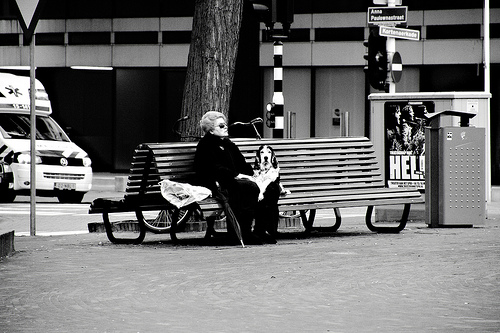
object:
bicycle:
[133, 117, 310, 232]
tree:
[151, 0, 246, 222]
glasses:
[212, 122, 230, 128]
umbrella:
[211, 180, 246, 248]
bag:
[157, 178, 212, 209]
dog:
[251, 143, 291, 201]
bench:
[87, 136, 426, 244]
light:
[374, 52, 384, 64]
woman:
[191, 110, 281, 244]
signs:
[377, 26, 420, 42]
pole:
[384, 0, 396, 93]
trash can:
[423, 109, 487, 228]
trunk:
[181, 0, 243, 141]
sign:
[367, 6, 409, 24]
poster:
[384, 101, 434, 190]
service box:
[366, 91, 492, 202]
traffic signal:
[363, 28, 388, 91]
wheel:
[135, 208, 193, 233]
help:
[389, 154, 426, 180]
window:
[312, 66, 366, 139]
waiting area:
[0, 119, 500, 310]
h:
[388, 155, 400, 179]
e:
[399, 156, 411, 179]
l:
[410, 155, 419, 183]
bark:
[177, 0, 244, 141]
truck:
[0, 72, 94, 203]